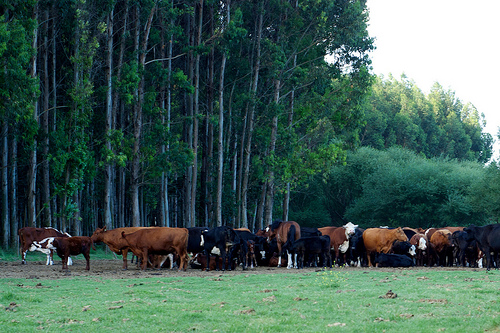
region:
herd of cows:
[14, 217, 499, 268]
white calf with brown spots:
[25, 239, 67, 268]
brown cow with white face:
[327, 219, 357, 261]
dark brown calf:
[51, 234, 91, 269]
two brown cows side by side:
[87, 221, 191, 265]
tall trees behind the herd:
[0, 4, 365, 231]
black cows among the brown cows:
[188, 210, 499, 270]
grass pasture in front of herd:
[18, 274, 499, 323]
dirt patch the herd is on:
[9, 254, 493, 273]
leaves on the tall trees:
[10, 1, 362, 204]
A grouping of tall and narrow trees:
[31, 6, 311, 218]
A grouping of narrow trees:
[38, 5, 289, 219]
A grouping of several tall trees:
[20, 8, 281, 227]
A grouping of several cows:
[11, 217, 499, 272]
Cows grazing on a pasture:
[21, 204, 416, 323]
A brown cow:
[118, 226, 189, 269]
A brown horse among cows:
[264, 215, 333, 272]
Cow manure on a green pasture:
[364, 279, 429, 321]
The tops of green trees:
[366, 64, 485, 153]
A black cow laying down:
[368, 249, 415, 270]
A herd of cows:
[13, 221, 498, 268]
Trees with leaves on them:
[0, 0, 375, 251]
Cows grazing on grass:
[0, 221, 496, 327]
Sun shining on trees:
[365, 71, 490, 157]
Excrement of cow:
[375, 286, 395, 297]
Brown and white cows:
[15, 225, 187, 270]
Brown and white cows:
[15, 225, 90, 270]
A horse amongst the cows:
[262, 216, 297, 266]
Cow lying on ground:
[372, 250, 412, 265]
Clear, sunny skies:
[378, 0, 493, 70]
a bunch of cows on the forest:
[12, 215, 498, 286]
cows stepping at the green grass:
[283, 284, 497, 331]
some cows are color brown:
[93, 219, 187, 279]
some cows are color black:
[201, 228, 269, 270]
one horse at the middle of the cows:
[260, 222, 307, 268]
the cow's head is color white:
[28, 234, 70, 269]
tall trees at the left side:
[0, 1, 382, 217]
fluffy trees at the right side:
[342, 74, 497, 221]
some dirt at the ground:
[98, 284, 298, 329]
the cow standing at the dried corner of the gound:
[10, 261, 103, 278]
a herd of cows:
[16, 200, 499, 279]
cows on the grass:
[12, 213, 498, 275]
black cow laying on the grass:
[365, 243, 420, 270]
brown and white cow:
[10, 218, 91, 279]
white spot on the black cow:
[196, 229, 207, 246]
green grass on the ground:
[2, 242, 497, 330]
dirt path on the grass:
[0, 257, 498, 274]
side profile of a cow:
[111, 225, 192, 269]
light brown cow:
[358, 225, 411, 268]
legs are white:
[283, 252, 303, 269]